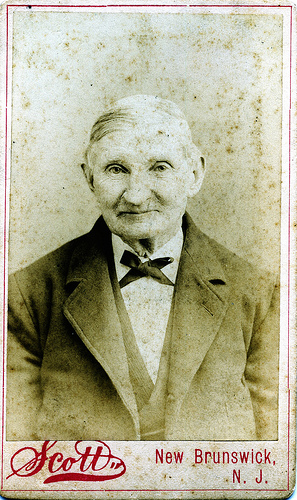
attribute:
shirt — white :
[113, 235, 185, 374]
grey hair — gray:
[84, 95, 201, 166]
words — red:
[6, 440, 126, 483]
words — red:
[153, 448, 183, 462]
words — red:
[193, 448, 271, 464]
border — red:
[5, 5, 290, 486]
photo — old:
[9, 11, 288, 497]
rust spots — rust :
[145, 463, 219, 493]